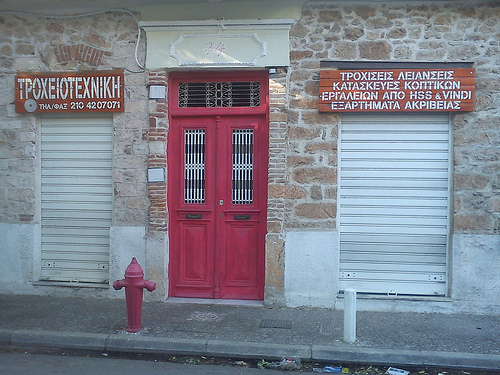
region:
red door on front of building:
[160, 65, 277, 302]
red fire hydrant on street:
[106, 256, 156, 334]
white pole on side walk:
[338, 285, 357, 345]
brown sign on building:
[10, 72, 126, 114]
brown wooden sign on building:
[317, 68, 474, 110]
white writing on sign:
[325, 66, 476, 104]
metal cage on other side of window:
[187, 128, 206, 197]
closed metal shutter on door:
[37, 119, 112, 280]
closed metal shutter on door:
[358, 123, 448, 314]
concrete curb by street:
[148, 332, 257, 352]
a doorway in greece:
[34, 35, 492, 353]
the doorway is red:
[131, 25, 299, 339]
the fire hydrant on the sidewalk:
[104, 246, 171, 344]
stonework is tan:
[60, 29, 418, 293]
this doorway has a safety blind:
[311, 83, 471, 338]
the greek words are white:
[274, 42, 491, 142]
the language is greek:
[307, 36, 495, 164]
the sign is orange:
[298, 16, 452, 164]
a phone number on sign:
[11, 52, 162, 172]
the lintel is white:
[132, 11, 326, 115]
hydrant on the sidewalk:
[111, 258, 157, 337]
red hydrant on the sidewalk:
[112, 256, 154, 333]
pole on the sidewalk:
[336, 286, 358, 342]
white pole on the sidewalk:
[343, 287, 355, 348]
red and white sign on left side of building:
[13, 73, 124, 112]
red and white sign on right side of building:
[317, 62, 477, 108]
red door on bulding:
[171, 71, 262, 301]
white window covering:
[339, 118, 448, 297]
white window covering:
[38, 116, 108, 289]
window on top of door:
[176, 80, 257, 105]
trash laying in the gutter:
[148, 358, 420, 373]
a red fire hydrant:
[116, 256, 162, 350]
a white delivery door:
[313, 47, 478, 305]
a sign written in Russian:
[16, 57, 136, 134]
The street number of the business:
[119, 13, 313, 68]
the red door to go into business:
[171, 78, 271, 303]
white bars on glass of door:
[181, 130, 213, 217]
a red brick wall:
[298, 30, 338, 225]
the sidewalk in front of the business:
[21, 295, 497, 363]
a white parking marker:
[341, 280, 378, 356]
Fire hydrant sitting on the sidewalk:
[81, 254, 169, 331]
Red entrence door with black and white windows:
[167, 71, 264, 300]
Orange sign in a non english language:
[319, 69, 475, 111]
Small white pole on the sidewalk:
[341, 289, 403, 351]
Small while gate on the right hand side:
[340, 114, 452, 295]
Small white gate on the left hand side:
[37, 116, 107, 287]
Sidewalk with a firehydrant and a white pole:
[0, 262, 491, 371]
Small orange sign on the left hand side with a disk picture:
[13, 72, 124, 114]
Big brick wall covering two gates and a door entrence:
[9, 2, 499, 279]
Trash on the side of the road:
[257, 358, 468, 373]